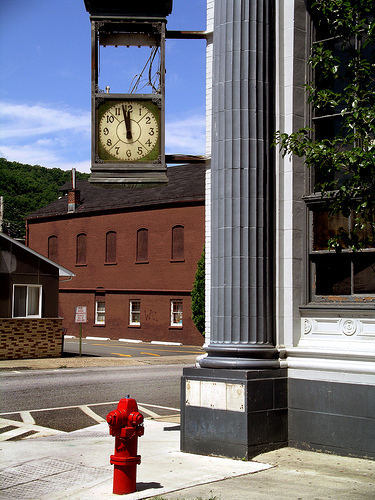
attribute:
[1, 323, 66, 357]
brown bricks — patterned, red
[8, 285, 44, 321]
white window — framed